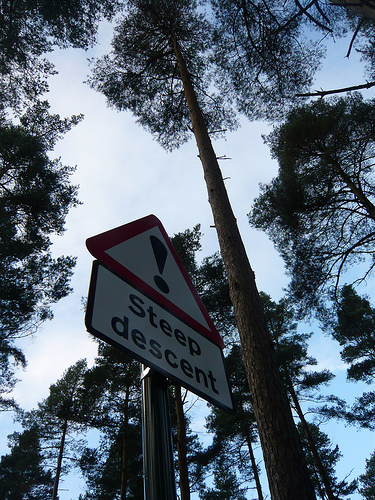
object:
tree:
[82, 0, 332, 160]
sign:
[85, 212, 239, 439]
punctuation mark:
[145, 231, 172, 297]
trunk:
[178, 77, 324, 494]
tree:
[223, 0, 371, 119]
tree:
[326, 281, 372, 497]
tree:
[256, 281, 334, 496]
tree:
[284, 414, 355, 499]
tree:
[0, 1, 86, 407]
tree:
[110, 221, 203, 496]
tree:
[32, 353, 93, 497]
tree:
[0, 416, 59, 498]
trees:
[91, 1, 337, 496]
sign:
[80, 212, 248, 420]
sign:
[93, 202, 227, 443]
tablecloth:
[83, 205, 238, 417]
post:
[142, 361, 174, 494]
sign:
[85, 264, 233, 411]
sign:
[81, 214, 239, 409]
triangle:
[83, 211, 225, 355]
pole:
[139, 373, 188, 498]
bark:
[180, 79, 201, 115]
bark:
[191, 121, 229, 172]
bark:
[204, 185, 249, 256]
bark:
[222, 270, 281, 369]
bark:
[245, 373, 317, 495]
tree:
[333, 282, 374, 403]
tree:
[241, 89, 374, 320]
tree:
[0, 100, 86, 413]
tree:
[5, 422, 55, 494]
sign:
[63, 187, 234, 424]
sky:
[0, 6, 369, 481]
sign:
[64, 195, 237, 441]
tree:
[81, 2, 327, 495]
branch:
[91, 45, 154, 114]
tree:
[82, 2, 327, 277]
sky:
[83, 139, 183, 209]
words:
[110, 290, 219, 398]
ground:
[135, 432, 237, 493]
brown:
[89, 482, 146, 499]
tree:
[0, 200, 90, 349]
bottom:
[117, 448, 164, 500]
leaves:
[36, 415, 122, 500]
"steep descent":
[116, 316, 219, 381]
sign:
[89, 217, 222, 446]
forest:
[4, 435, 344, 500]